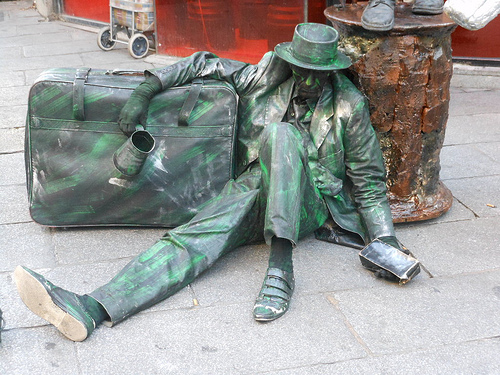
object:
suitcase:
[26, 68, 243, 228]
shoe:
[253, 266, 294, 321]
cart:
[97, 0, 158, 59]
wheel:
[98, 26, 118, 52]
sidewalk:
[1, 1, 499, 374]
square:
[23, 39, 140, 56]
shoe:
[359, 2, 398, 32]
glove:
[119, 74, 160, 136]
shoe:
[11, 264, 98, 341]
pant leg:
[257, 122, 328, 248]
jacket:
[147, 49, 397, 247]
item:
[358, 237, 420, 286]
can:
[112, 126, 157, 177]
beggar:
[10, 23, 421, 341]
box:
[358, 236, 421, 284]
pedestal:
[323, 1, 455, 226]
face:
[286, 63, 325, 98]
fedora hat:
[274, 20, 353, 71]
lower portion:
[380, 125, 447, 221]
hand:
[118, 75, 161, 134]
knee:
[259, 122, 308, 166]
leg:
[10, 180, 265, 343]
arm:
[119, 51, 286, 134]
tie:
[291, 97, 311, 137]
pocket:
[318, 150, 349, 168]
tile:
[315, 265, 499, 359]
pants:
[85, 122, 329, 325]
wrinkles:
[162, 210, 232, 254]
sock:
[268, 234, 293, 267]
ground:
[1, 0, 498, 375]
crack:
[1, 148, 25, 157]